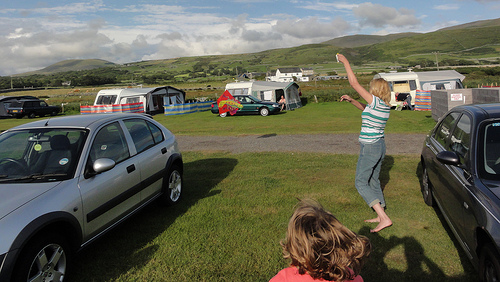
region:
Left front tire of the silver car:
[8, 226, 80, 278]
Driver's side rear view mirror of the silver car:
[88, 157, 118, 172]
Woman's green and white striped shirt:
[356, 93, 387, 145]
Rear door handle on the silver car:
[158, 146, 170, 156]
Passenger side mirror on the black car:
[431, 146, 463, 170]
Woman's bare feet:
[361, 213, 396, 235]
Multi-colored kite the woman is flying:
[209, 86, 250, 124]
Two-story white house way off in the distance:
[265, 63, 312, 85]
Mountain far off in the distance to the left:
[11, 54, 138, 74]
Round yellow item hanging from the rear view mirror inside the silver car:
[31, 141, 44, 155]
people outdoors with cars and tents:
[40, 47, 466, 249]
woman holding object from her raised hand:
[325, 35, 395, 235]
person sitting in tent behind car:
[205, 71, 305, 121]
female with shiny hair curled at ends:
[272, 200, 382, 275]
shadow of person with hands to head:
[355, 225, 457, 270]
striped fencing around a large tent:
[75, 81, 205, 111]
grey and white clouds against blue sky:
[10, 6, 296, 38]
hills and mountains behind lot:
[46, 16, 481, 71]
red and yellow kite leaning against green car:
[210, 81, 255, 121]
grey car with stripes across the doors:
[18, 107, 213, 247]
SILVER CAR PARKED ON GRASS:
[0, 105, 187, 276]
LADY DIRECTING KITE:
[315, 50, 420, 236]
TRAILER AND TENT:
[210, 78, 300, 120]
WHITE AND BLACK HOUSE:
[265, 65, 315, 85]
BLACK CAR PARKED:
[415, 91, 497, 266]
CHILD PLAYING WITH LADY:
[265, 197, 385, 273]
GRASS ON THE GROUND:
[145, 151, 457, 277]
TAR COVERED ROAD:
[195, 125, 431, 152]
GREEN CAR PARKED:
[205, 95, 288, 116]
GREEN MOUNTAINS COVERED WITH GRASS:
[198, 0, 498, 86]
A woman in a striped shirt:
[334, 45, 411, 231]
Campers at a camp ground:
[21, 43, 466, 243]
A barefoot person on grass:
[338, 128, 407, 234]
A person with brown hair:
[277, 201, 372, 281]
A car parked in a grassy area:
[8, 110, 256, 260]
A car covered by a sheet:
[208, 90, 279, 125]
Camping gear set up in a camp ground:
[88, 88, 195, 116]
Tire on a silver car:
[151, 148, 188, 208]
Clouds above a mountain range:
[44, 16, 322, 68]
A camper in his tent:
[263, 80, 304, 114]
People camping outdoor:
[14, 23, 495, 276]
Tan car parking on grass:
[2, 112, 197, 278]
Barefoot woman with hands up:
[329, 41, 406, 236]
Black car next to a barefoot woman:
[418, 105, 498, 280]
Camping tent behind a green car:
[97, 81, 219, 114]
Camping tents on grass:
[95, 77, 486, 111]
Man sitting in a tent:
[273, 90, 288, 112]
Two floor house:
[267, 66, 317, 79]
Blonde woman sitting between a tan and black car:
[269, 201, 371, 280]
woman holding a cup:
[331, 40, 408, 239]